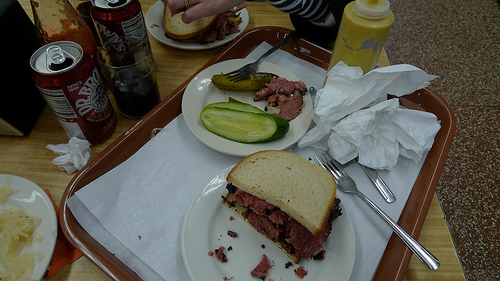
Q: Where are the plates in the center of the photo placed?
A: On a tray.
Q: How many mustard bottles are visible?
A: One.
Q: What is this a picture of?
A: A meal.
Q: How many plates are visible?
A: Four.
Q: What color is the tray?
A: Brown.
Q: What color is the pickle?
A: Green.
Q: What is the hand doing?
A: Reaching for the sandwich.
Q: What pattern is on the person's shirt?
A: Stripes.